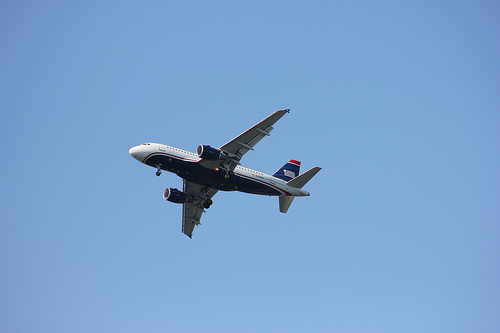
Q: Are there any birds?
A: No, there are no birds.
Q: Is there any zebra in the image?
A: No, there are no zebras.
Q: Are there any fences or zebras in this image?
A: No, there are no zebras or fences.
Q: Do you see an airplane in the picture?
A: Yes, there is an airplane.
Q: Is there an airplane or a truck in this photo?
A: Yes, there is an airplane.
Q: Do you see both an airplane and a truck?
A: No, there is an airplane but no trucks.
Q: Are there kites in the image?
A: No, there are no kites.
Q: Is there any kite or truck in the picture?
A: No, there are no kites or trucks.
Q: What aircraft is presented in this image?
A: The aircraft is an airplane.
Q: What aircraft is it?
A: The aircraft is an airplane.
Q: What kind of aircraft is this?
A: This is an airplane.